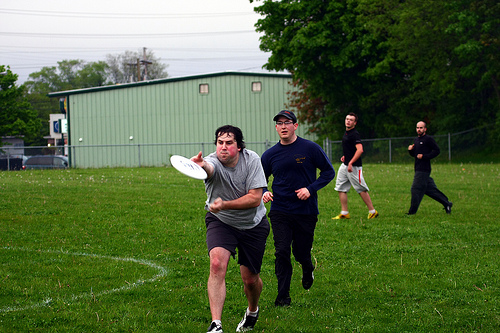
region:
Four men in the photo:
[170, 86, 464, 331]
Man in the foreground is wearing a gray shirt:
[183, 148, 275, 242]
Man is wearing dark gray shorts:
[193, 202, 275, 284]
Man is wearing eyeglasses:
[261, 103, 299, 135]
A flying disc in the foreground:
[161, 140, 211, 193]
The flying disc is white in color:
[156, 140, 216, 193]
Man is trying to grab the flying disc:
[164, 115, 284, 331]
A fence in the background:
[3, 120, 499, 170]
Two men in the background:
[331, 100, 469, 227]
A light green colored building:
[42, 60, 326, 171]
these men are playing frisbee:
[144, 96, 481, 311]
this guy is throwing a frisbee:
[165, 104, 275, 316]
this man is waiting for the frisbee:
[254, 94, 336, 314]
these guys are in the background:
[334, 99, 473, 276]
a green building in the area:
[45, 55, 330, 182]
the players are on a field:
[17, 116, 480, 332]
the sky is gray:
[24, 8, 284, 39]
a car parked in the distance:
[7, 110, 82, 186]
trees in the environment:
[249, 5, 479, 117]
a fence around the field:
[4, 134, 155, 170]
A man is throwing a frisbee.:
[167, 122, 275, 332]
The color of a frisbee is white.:
[167, 149, 210, 185]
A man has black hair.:
[209, 123, 251, 161]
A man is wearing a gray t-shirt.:
[192, 143, 268, 234]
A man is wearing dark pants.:
[200, 210, 274, 275]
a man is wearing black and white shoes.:
[205, 307, 262, 332]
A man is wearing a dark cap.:
[270, 108, 302, 129]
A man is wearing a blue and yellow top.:
[258, 135, 338, 203]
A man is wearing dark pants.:
[259, 200, 321, 309]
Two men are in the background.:
[327, 110, 457, 225]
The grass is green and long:
[335, 233, 452, 312]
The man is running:
[163, 213, 254, 323]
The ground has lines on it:
[43, 225, 153, 325]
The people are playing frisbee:
[163, 135, 220, 200]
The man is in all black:
[390, 107, 480, 234]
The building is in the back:
[149, 75, 259, 186]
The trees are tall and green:
[9, 61, 69, 130]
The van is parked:
[18, 129, 95, 203]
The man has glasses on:
[267, 101, 304, 145]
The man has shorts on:
[333, 157, 374, 204]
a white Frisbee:
[171, 153, 207, 181]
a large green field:
[0, 152, 496, 330]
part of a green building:
[60, 76, 319, 168]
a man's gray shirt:
[196, 147, 272, 225]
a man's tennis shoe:
[231, 305, 263, 331]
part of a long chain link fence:
[0, 137, 496, 172]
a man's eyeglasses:
[273, 118, 295, 129]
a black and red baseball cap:
[265, 109, 297, 124]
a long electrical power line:
[0, 25, 267, 42]